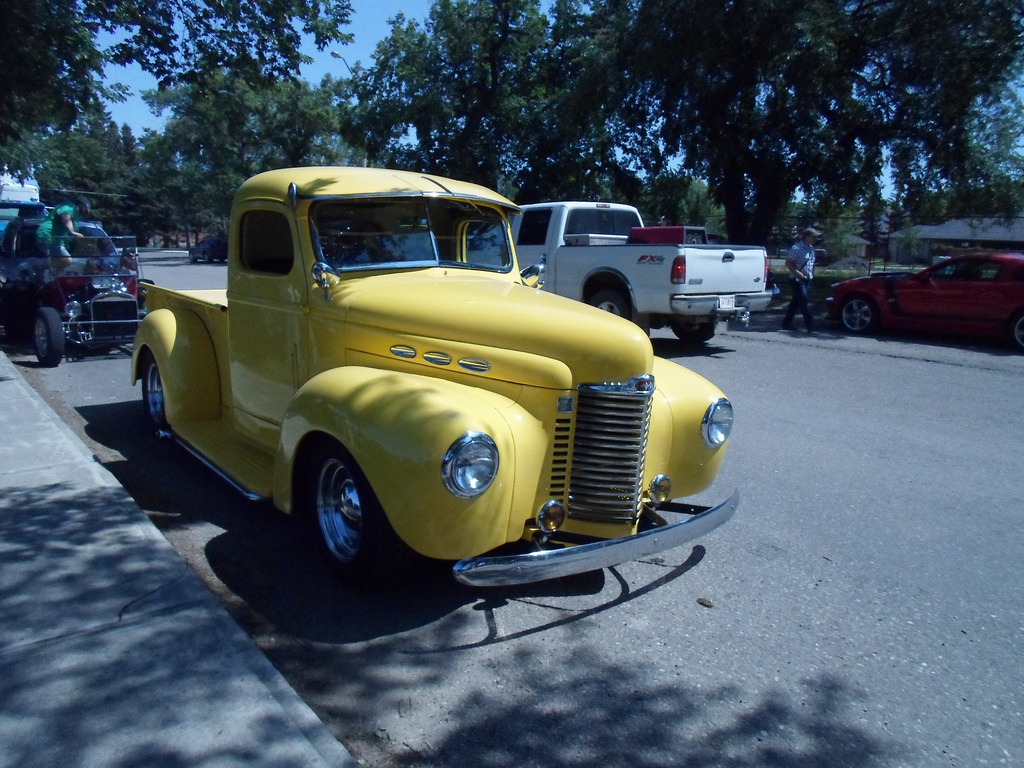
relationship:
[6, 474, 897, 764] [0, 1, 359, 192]
shadow of tree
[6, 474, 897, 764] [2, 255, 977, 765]
shadow on pavement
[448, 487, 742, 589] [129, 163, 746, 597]
part mounted on classic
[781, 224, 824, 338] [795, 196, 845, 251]
man wearing cap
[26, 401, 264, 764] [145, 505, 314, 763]
sidewalk with curb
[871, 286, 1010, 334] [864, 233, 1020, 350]
stripe in car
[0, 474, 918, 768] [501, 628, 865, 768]
shadow of trees on ground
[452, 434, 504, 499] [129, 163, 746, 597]
headlight in front of classic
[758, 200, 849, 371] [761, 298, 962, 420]
man walking across road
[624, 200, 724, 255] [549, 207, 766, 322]
dog cage on back of truck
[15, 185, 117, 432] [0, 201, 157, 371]
person standing on back of car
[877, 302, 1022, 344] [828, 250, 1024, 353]
bottom of a red car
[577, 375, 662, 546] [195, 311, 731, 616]
silver grill in front of truck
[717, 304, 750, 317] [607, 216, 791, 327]
tag on back of truck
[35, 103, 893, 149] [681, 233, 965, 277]
trees above cars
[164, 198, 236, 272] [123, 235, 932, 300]
car sitting on side of road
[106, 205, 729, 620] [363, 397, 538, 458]
classic yellow truck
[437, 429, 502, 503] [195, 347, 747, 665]
headlight on truck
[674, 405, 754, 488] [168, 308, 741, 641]
headlight on truck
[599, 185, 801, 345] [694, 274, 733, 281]
truck wearing newer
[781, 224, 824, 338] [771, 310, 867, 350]
man in blue shirt walking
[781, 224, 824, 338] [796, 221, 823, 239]
man wearing cap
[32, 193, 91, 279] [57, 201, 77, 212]
person wearing hat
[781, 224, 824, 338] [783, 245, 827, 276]
man wearing shirt